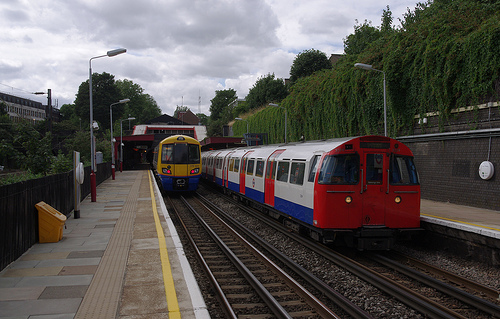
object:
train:
[197, 133, 422, 251]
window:
[273, 156, 289, 184]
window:
[288, 160, 305, 184]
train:
[154, 132, 205, 194]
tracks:
[151, 158, 499, 316]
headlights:
[339, 194, 353, 207]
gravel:
[331, 270, 413, 319]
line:
[145, 169, 186, 317]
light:
[80, 46, 130, 206]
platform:
[7, 162, 199, 318]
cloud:
[86, 3, 177, 30]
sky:
[2, 3, 118, 55]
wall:
[400, 102, 499, 214]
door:
[260, 152, 288, 209]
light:
[391, 194, 404, 205]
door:
[236, 146, 256, 195]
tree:
[73, 73, 131, 165]